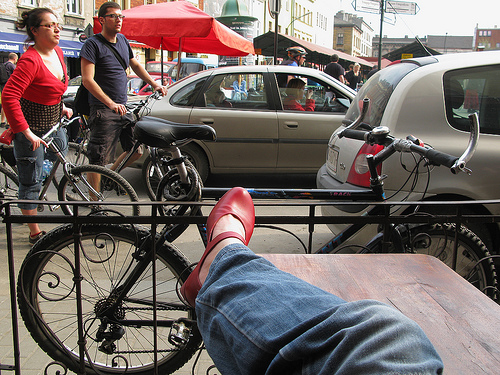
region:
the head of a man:
[90, 0, 122, 43]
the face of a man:
[93, 4, 125, 39]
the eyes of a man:
[103, 2, 130, 32]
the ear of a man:
[94, 8, 111, 32]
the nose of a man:
[106, 11, 131, 32]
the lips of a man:
[89, 11, 139, 45]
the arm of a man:
[62, 41, 111, 145]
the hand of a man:
[99, 87, 141, 122]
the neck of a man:
[99, 20, 128, 39]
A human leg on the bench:
[181, 185, 446, 369]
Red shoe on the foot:
[180, 186, 256, 307]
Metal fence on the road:
[4, 192, 496, 372]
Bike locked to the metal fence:
[16, 97, 496, 371]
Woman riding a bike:
[1, 5, 75, 247]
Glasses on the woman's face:
[31, 21, 60, 28]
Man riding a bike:
[79, 2, 169, 212]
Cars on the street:
[113, 50, 499, 297]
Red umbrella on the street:
[92, 1, 254, 88]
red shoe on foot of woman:
[182, 185, 262, 313]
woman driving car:
[273, 71, 332, 128]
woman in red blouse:
[12, 5, 72, 163]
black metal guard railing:
[5, 196, 178, 373]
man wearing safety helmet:
[281, 42, 310, 67]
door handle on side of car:
[279, 118, 307, 133]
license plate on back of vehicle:
[323, 144, 340, 180]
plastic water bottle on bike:
[33, 157, 56, 188]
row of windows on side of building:
[472, 25, 498, 39]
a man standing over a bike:
[71, 0, 207, 211]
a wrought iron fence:
[7, 194, 199, 374]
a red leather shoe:
[177, 181, 257, 304]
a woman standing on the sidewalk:
[3, 1, 74, 247]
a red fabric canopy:
[94, 0, 256, 60]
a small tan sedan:
[111, 63, 381, 185]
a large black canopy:
[251, 28, 383, 72]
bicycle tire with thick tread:
[18, 219, 213, 374]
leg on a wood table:
[180, 184, 495, 374]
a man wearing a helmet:
[283, 44, 311, 66]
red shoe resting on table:
[175, 181, 257, 308]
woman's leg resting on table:
[173, 179, 451, 374]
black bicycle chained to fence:
[14, 92, 498, 372]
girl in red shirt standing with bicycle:
[0, 2, 140, 252]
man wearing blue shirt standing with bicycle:
[48, 0, 204, 215]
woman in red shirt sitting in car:
[278, 74, 318, 116]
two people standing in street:
[0, 0, 209, 250]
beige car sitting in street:
[96, 62, 363, 194]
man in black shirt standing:
[322, 52, 348, 87]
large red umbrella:
[87, 0, 257, 87]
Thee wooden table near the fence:
[222, 240, 480, 372]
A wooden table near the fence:
[250, 236, 470, 371]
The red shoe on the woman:
[179, 185, 282, 282]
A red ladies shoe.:
[181, 178, 272, 318]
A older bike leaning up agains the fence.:
[13, 95, 499, 372]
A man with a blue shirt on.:
[75, 3, 150, 114]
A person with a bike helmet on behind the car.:
[286, 36, 309, 67]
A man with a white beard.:
[351, 62, 363, 79]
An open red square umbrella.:
[88, 3, 265, 72]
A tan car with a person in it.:
[88, 58, 374, 192]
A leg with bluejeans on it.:
[191, 240, 458, 374]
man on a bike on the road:
[78, 0, 168, 180]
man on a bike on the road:
[9, 10, 96, 211]